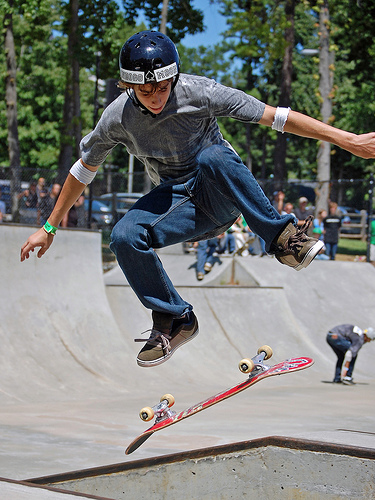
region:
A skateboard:
[129, 312, 277, 480]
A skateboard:
[182, 319, 238, 443]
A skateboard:
[140, 328, 233, 460]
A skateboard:
[171, 359, 255, 487]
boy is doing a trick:
[47, 25, 289, 460]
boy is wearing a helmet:
[83, 39, 215, 127]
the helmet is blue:
[109, 15, 202, 132]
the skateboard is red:
[95, 333, 302, 462]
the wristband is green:
[23, 206, 70, 259]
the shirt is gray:
[60, 65, 252, 179]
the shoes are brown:
[97, 210, 370, 345]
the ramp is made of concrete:
[61, 218, 250, 429]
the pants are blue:
[93, 163, 272, 347]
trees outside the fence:
[7, 9, 304, 267]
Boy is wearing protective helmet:
[115, 24, 188, 92]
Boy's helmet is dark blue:
[96, 24, 198, 82]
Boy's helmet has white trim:
[109, 61, 190, 84]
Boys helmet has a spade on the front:
[136, 65, 161, 82]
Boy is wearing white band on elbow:
[52, 147, 105, 203]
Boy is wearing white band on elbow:
[267, 102, 292, 138]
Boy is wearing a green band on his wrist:
[25, 208, 62, 237]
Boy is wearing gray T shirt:
[66, 77, 279, 175]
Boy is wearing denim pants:
[111, 156, 303, 309]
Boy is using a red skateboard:
[109, 343, 332, 454]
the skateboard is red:
[205, 400, 213, 412]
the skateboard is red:
[181, 383, 197, 422]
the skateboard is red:
[185, 408, 195, 417]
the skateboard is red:
[202, 405, 208, 415]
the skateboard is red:
[192, 410, 199, 417]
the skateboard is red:
[196, 408, 202, 416]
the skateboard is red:
[190, 409, 197, 421]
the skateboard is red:
[182, 415, 194, 425]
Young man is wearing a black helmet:
[100, 17, 205, 94]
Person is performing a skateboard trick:
[104, 338, 326, 471]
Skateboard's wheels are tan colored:
[118, 342, 279, 423]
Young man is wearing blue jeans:
[111, 137, 301, 321]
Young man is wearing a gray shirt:
[57, 72, 278, 213]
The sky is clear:
[188, 0, 223, 49]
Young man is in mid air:
[8, 43, 371, 382]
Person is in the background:
[316, 316, 372, 391]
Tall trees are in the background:
[0, 10, 370, 216]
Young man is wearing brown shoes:
[120, 211, 329, 373]